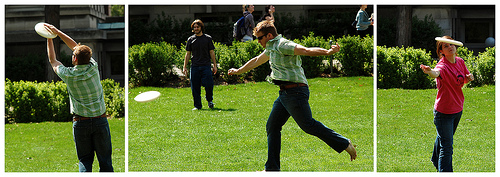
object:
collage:
[7, 5, 496, 175]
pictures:
[373, 5, 498, 174]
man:
[44, 24, 114, 171]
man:
[225, 18, 358, 171]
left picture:
[5, 5, 125, 175]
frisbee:
[34, 22, 60, 39]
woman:
[420, 35, 474, 172]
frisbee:
[434, 37, 465, 47]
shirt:
[433, 57, 472, 115]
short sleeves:
[435, 65, 445, 81]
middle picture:
[129, 6, 373, 173]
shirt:
[261, 33, 310, 84]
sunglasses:
[252, 33, 268, 41]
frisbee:
[133, 90, 161, 102]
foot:
[346, 143, 358, 161]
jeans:
[264, 83, 351, 172]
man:
[182, 19, 218, 110]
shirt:
[185, 33, 217, 68]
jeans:
[190, 65, 215, 107]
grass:
[132, 77, 369, 172]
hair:
[190, 19, 205, 28]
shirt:
[54, 57, 107, 117]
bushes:
[129, 41, 187, 86]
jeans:
[71, 115, 114, 172]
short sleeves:
[56, 63, 69, 82]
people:
[351, 5, 374, 38]